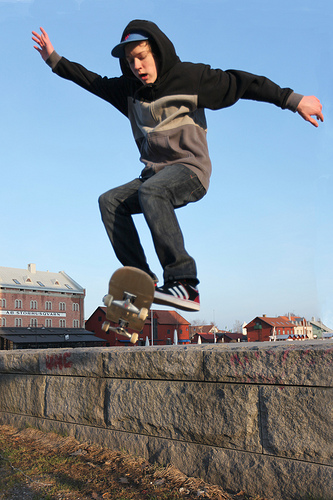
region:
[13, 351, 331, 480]
a rustic blocks wall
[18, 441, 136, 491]
the ground is rocky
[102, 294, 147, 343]
the four skateboard wheels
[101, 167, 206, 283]
this is a black jeans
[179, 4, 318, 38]
a blue sky in the background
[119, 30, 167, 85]
the head of the skater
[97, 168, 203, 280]
the skater legs bent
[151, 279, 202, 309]
one sneaker of the skater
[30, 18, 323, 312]
A boy in the air.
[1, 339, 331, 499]
A small brick wall.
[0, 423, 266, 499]
Grass by a wall.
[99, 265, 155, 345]
A skateboard in the air.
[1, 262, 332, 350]
Buildings behind a boy.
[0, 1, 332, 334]
A clear blue sky.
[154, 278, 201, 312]
A shoe on a boy.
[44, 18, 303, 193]
A hoodie shirt on a boy.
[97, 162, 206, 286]
A pair of jeans.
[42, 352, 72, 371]
Graffiti on a wall.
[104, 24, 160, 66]
boy wearing a blue hat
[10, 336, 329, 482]
Brick wall in the yard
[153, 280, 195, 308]
man wearing black and white sneakers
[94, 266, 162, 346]
skateboard on the wall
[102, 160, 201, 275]
boy wearing blue jeans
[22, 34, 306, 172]
man wearing a black and gray sweat shirt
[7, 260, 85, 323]
Large building with multiple windows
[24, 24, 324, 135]
boy with his arms out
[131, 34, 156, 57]
boy with blonde hair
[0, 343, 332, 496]
a short stone brick wall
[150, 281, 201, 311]
a red white and black shoe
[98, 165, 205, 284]
a pair of blue jeans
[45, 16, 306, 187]
a grey and black sweatshirt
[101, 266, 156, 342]
a beige skateboard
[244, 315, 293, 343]
large red building in distance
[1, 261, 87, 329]
large building in distance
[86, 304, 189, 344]
large red building in distance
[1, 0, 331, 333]
a clear blue sky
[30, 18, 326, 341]
a young boy performing a trick on skateboard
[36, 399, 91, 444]
Cut up tomatoe in the folded bread.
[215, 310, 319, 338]
Cut up tomatoe in the folded bread.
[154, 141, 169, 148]
Cut up tomatoe in the folded bread.